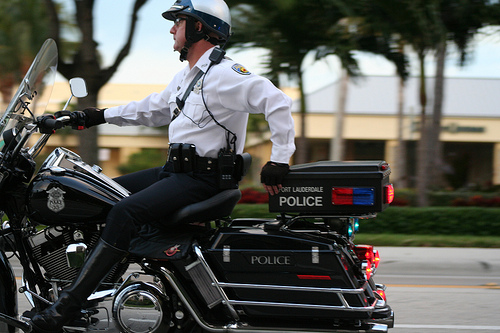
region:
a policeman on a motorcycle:
[3, 3, 406, 327]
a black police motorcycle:
[0, 43, 400, 331]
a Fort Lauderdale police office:
[2, 0, 402, 327]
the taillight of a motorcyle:
[351, 240, 383, 279]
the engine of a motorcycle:
[20, 214, 77, 281]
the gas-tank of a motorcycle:
[31, 148, 127, 224]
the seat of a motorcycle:
[164, 190, 246, 227]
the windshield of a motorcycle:
[3, 33, 64, 169]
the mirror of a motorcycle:
[66, 73, 91, 98]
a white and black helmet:
[166, 2, 236, 22]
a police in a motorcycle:
[3, 0, 418, 332]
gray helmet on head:
[157, 0, 245, 86]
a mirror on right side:
[63, 73, 96, 100]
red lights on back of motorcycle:
[343, 225, 396, 302]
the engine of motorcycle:
[20, 228, 174, 331]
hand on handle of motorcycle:
[71, 94, 112, 129]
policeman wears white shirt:
[26, 2, 311, 310]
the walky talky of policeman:
[192, 43, 245, 178]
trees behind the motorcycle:
[3, 0, 498, 330]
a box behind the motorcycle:
[263, 152, 403, 233]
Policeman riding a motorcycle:
[1, 0, 400, 332]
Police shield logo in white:
[43, 185, 67, 213]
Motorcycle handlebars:
[33, 107, 100, 133]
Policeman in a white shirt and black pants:
[33, 0, 297, 327]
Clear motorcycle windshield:
[2, 36, 59, 158]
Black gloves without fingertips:
[258, 163, 290, 189]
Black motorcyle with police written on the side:
[3, 35, 398, 330]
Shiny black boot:
[31, 238, 131, 331]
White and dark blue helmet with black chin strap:
[162, 0, 232, 60]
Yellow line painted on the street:
[384, 278, 499, 290]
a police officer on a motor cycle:
[1, 3, 408, 326]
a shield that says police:
[39, 184, 79, 217]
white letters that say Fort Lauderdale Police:
[271, 181, 333, 216]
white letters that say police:
[249, 251, 293, 269]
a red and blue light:
[329, 183, 376, 211]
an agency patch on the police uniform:
[228, 58, 258, 81]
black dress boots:
[29, 233, 131, 328]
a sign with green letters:
[406, 110, 490, 146]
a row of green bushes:
[397, 195, 494, 237]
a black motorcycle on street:
[2, 38, 397, 331]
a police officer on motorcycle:
[0, 0, 401, 331]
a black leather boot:
[30, 228, 122, 329]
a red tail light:
[386, 183, 393, 203]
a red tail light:
[375, 251, 380, 265]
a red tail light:
[364, 261, 371, 278]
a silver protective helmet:
[162, 0, 231, 37]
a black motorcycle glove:
[75, 107, 105, 128]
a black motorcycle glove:
[260, 161, 289, 184]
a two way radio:
[207, 43, 227, 65]